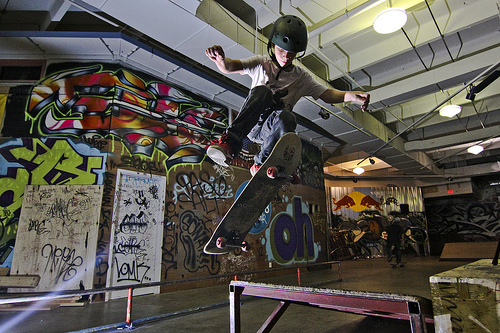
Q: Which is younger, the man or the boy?
A: The boy is younger than the man.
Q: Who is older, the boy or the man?
A: The man is older than the boy.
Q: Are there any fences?
A: No, there are no fences.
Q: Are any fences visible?
A: No, there are no fences.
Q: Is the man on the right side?
A: Yes, the man is on the right of the image.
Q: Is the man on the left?
A: No, the man is on the right of the image.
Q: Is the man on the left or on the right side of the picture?
A: The man is on the right of the image.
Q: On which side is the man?
A: The man is on the right of the image.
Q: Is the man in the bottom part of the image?
A: Yes, the man is in the bottom of the image.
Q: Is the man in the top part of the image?
A: No, the man is in the bottom of the image.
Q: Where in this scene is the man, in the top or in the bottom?
A: The man is in the bottom of the image.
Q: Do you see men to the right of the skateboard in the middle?
A: Yes, there is a man to the right of the skateboard.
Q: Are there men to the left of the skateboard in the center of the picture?
A: No, the man is to the right of the skateboard.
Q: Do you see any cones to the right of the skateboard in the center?
A: No, there is a man to the right of the skateboard.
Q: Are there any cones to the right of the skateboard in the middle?
A: No, there is a man to the right of the skateboard.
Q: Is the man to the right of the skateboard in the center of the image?
A: Yes, the man is to the right of the skateboard.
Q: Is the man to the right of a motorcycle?
A: No, the man is to the right of the skateboard.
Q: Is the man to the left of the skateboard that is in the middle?
A: No, the man is to the right of the skateboard.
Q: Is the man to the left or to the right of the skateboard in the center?
A: The man is to the right of the skateboard.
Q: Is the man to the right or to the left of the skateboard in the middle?
A: The man is to the right of the skateboard.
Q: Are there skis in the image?
A: No, there are no skis.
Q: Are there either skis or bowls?
A: No, there are no skis or bowls.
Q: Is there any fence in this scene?
A: No, there are no fences.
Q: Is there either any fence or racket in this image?
A: No, there are no fences or rackets.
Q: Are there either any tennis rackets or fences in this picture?
A: No, there are no fences or tennis rackets.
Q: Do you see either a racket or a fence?
A: No, there are no fences or rackets.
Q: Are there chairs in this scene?
A: No, there are no chairs.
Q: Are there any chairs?
A: No, there are no chairs.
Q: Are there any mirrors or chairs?
A: No, there are no chairs or mirrors.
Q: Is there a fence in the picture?
A: No, there are no fences.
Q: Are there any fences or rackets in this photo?
A: No, there are no fences or rackets.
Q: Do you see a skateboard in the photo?
A: Yes, there is a skateboard.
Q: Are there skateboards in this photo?
A: Yes, there is a skateboard.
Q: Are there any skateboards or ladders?
A: Yes, there is a skateboard.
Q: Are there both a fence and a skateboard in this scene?
A: No, there is a skateboard but no fences.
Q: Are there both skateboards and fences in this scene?
A: No, there is a skateboard but no fences.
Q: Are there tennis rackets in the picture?
A: No, there are no tennis rackets.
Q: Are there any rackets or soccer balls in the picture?
A: No, there are no rackets or soccer balls.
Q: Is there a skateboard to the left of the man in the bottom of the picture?
A: Yes, there is a skateboard to the left of the man.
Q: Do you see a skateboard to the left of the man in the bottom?
A: Yes, there is a skateboard to the left of the man.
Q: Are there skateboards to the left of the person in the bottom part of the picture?
A: Yes, there is a skateboard to the left of the man.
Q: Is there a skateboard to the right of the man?
A: No, the skateboard is to the left of the man.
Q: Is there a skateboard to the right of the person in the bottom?
A: No, the skateboard is to the left of the man.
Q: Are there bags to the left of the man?
A: No, there is a skateboard to the left of the man.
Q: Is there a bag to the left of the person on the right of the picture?
A: No, there is a skateboard to the left of the man.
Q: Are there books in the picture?
A: No, there are no books.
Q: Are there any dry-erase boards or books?
A: No, there are no books or dry-erase boards.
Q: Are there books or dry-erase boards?
A: No, there are no books or dry-erase boards.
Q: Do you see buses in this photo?
A: No, there are no buses.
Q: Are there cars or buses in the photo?
A: No, there are no buses or cars.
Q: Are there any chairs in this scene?
A: No, there are no chairs.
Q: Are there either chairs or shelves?
A: No, there are no chairs or shelves.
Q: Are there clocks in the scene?
A: No, there are no clocks.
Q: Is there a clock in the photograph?
A: No, there are no clocks.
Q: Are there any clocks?
A: No, there are no clocks.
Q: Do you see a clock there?
A: No, there are no clocks.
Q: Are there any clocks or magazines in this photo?
A: No, there are no clocks or magazines.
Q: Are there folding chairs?
A: No, there are no folding chairs.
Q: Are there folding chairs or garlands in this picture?
A: No, there are no folding chairs or garlands.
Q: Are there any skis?
A: No, there are no skis.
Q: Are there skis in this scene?
A: No, there are no skis.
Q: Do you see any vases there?
A: No, there are no vases.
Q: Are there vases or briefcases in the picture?
A: No, there are no vases or briefcases.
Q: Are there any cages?
A: No, there are no cages.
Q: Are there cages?
A: No, there are no cages.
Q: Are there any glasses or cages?
A: No, there are no cages or glasses.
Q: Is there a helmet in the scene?
A: Yes, there is a helmet.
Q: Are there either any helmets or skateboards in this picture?
A: Yes, there is a helmet.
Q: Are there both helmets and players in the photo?
A: No, there is a helmet but no players.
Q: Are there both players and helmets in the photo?
A: No, there is a helmet but no players.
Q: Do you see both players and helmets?
A: No, there is a helmet but no players.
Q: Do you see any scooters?
A: No, there are no scooters.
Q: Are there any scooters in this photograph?
A: No, there are no scooters.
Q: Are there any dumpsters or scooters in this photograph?
A: No, there are no scooters or dumpsters.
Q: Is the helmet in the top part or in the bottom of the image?
A: The helmet is in the top of the image.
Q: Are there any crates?
A: No, there are no crates.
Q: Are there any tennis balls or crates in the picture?
A: No, there are no crates or tennis balls.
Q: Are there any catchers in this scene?
A: No, there are no catchers.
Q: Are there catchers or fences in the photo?
A: No, there are no catchers or fences.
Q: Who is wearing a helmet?
A: The boy is wearing a helmet.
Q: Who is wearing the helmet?
A: The boy is wearing a helmet.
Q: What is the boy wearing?
A: The boy is wearing a helmet.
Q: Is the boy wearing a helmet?
A: Yes, the boy is wearing a helmet.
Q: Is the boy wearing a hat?
A: No, the boy is wearing a helmet.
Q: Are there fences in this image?
A: No, there are no fences.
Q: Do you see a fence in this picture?
A: No, there are no fences.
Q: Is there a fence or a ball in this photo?
A: No, there are no fences or balls.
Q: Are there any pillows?
A: No, there are no pillows.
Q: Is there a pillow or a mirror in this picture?
A: No, there are no pillows or mirrors.